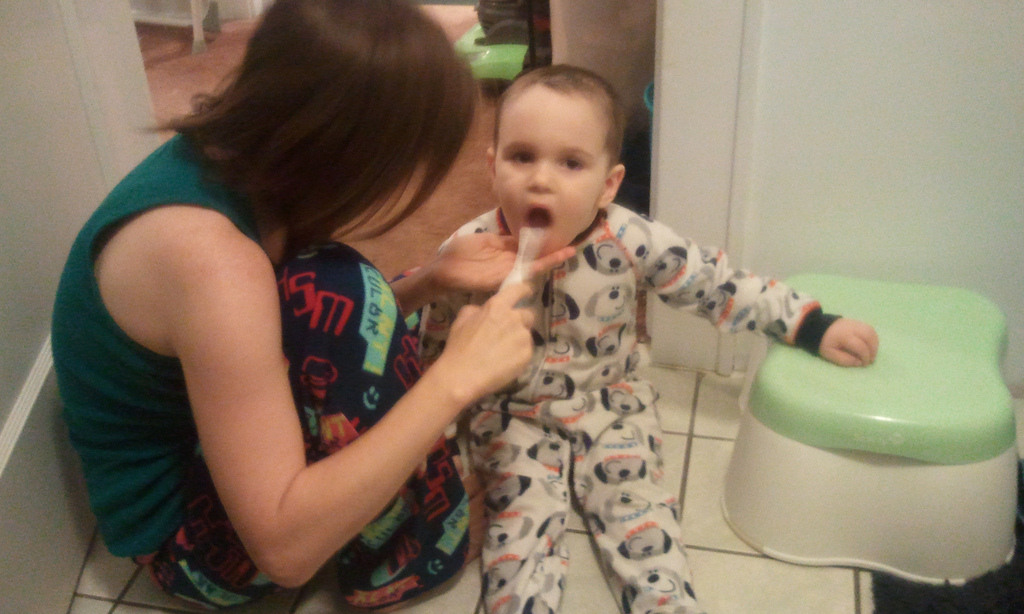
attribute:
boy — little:
[455, 59, 851, 610]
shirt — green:
[55, 136, 254, 551]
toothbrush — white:
[490, 217, 540, 289]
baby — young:
[415, 59, 880, 610]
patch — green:
[357, 258, 399, 379]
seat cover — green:
[746, 266, 993, 470]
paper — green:
[454, 24, 532, 85]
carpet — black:
[871, 452, 993, 606]